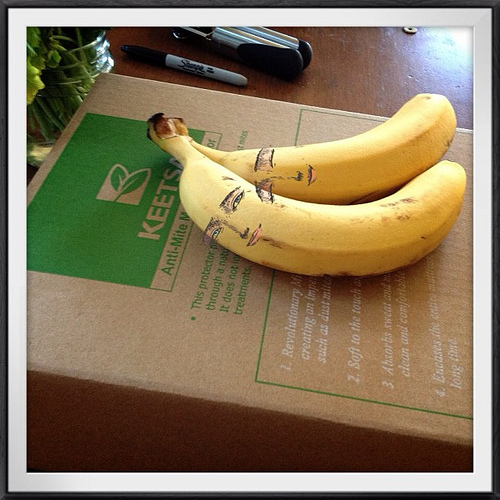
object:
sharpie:
[173, 55, 216, 79]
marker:
[119, 37, 249, 88]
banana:
[177, 156, 469, 280]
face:
[200, 184, 263, 250]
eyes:
[219, 184, 249, 217]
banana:
[169, 88, 460, 205]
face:
[250, 141, 320, 206]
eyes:
[251, 145, 278, 174]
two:
[133, 85, 469, 282]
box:
[5, 66, 496, 448]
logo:
[95, 158, 156, 209]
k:
[135, 219, 167, 242]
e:
[145, 205, 171, 225]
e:
[150, 193, 176, 209]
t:
[155, 176, 179, 197]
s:
[162, 164, 186, 183]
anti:
[159, 245, 181, 278]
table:
[318, 29, 470, 103]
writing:
[313, 277, 338, 368]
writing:
[230, 257, 255, 320]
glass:
[25, 25, 114, 145]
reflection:
[411, 21, 473, 87]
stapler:
[160, 26, 321, 85]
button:
[397, 21, 420, 37]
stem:
[140, 105, 191, 154]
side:
[44, 359, 375, 441]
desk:
[336, 43, 402, 97]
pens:
[223, 24, 315, 71]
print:
[157, 220, 191, 280]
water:
[28, 132, 54, 168]